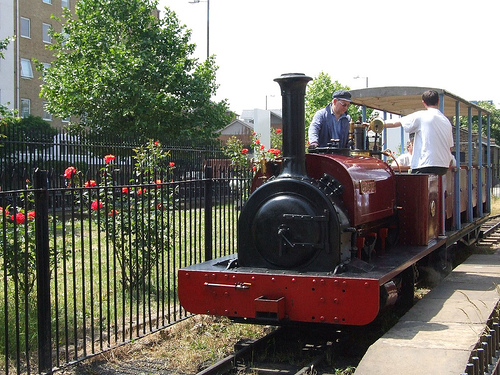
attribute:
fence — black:
[0, 173, 240, 373]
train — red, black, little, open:
[180, 54, 498, 325]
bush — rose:
[58, 130, 177, 294]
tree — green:
[26, 3, 233, 150]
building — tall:
[4, 1, 165, 135]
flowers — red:
[57, 146, 189, 216]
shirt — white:
[397, 103, 458, 175]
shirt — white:
[393, 106, 458, 167]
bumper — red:
[170, 252, 400, 335]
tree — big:
[30, 3, 239, 213]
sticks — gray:
[452, 108, 493, 228]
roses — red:
[61, 148, 184, 218]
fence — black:
[1, 117, 235, 371]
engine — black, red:
[170, 52, 433, 346]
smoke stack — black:
[270, 66, 317, 184]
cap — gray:
[326, 90, 356, 108]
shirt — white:
[397, 104, 464, 178]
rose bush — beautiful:
[57, 136, 188, 300]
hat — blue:
[327, 87, 355, 103]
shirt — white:
[396, 107, 456, 172]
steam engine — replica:
[230, 68, 402, 270]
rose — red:
[59, 161, 83, 181]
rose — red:
[85, 199, 106, 214]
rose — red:
[108, 206, 120, 216]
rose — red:
[98, 151, 114, 166]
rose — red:
[116, 186, 133, 198]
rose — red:
[132, 182, 152, 202]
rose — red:
[84, 178, 99, 187]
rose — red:
[150, 136, 165, 147]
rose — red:
[162, 161, 174, 168]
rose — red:
[148, 201, 164, 213]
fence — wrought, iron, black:
[0, 146, 292, 372]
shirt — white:
[391, 101, 461, 179]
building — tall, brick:
[0, 0, 167, 203]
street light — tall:
[182, 0, 222, 176]